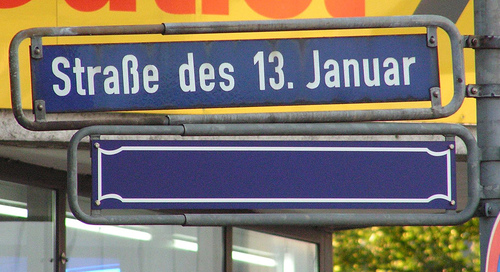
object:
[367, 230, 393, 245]
leaves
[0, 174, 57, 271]
glass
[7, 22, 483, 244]
signpost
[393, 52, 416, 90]
letters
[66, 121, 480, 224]
frame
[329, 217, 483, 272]
tree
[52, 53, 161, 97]
text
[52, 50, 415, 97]
text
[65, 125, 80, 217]
metal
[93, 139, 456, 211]
board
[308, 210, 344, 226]
metal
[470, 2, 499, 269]
pole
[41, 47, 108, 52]
metal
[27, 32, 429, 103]
sign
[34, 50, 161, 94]
spanish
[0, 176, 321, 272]
windows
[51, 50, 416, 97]
spanish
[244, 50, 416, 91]
spanish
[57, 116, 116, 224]
road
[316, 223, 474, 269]
background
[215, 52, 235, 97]
letter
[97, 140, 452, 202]
two